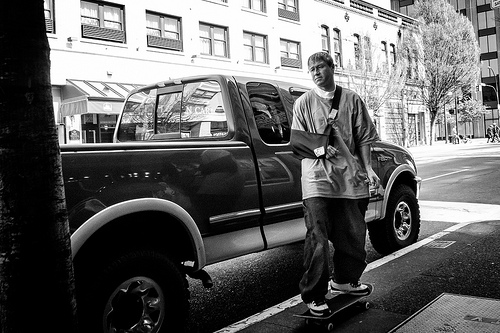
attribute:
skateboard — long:
[288, 281, 377, 325]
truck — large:
[68, 74, 425, 326]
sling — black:
[279, 123, 338, 164]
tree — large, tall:
[398, 0, 482, 141]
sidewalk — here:
[409, 140, 495, 159]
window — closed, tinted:
[242, 81, 293, 143]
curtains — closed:
[84, 4, 123, 18]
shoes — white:
[302, 282, 365, 313]